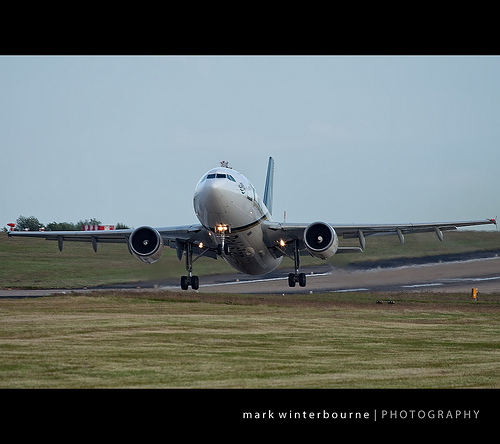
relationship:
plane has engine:
[8, 137, 492, 292] [294, 215, 351, 261]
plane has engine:
[8, 137, 492, 292] [125, 218, 178, 267]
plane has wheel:
[8, 137, 492, 292] [288, 265, 314, 293]